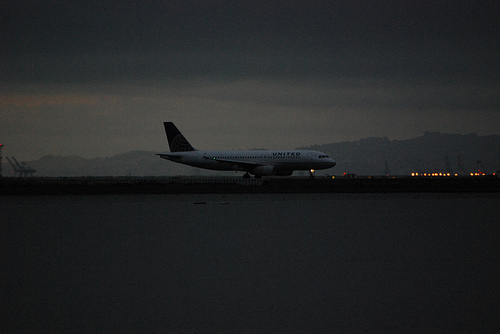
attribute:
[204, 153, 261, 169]
wing — large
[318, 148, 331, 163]
windshield —  jet's,  large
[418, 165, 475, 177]
lights — in a row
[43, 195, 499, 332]
concrete —  flat 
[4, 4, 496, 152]
cloudy sky — dark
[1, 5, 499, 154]
sky — blue gray